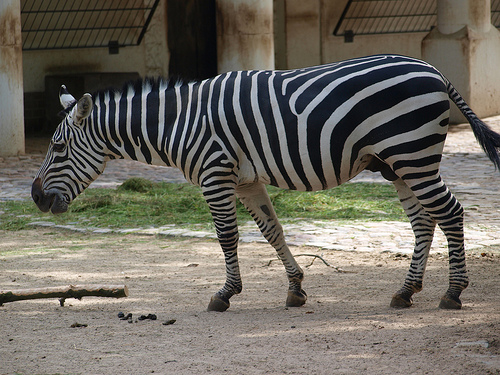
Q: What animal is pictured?
A: A zebra.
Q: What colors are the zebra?
A: Black and white.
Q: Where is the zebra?
A: In a zoo.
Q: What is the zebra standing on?
A: Dirt.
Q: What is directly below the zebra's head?
A: A branch.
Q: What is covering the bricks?
A: Grass clippings.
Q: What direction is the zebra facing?
A: Left.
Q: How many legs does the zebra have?
A: Four.